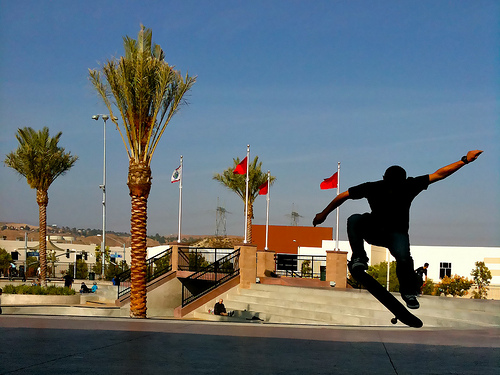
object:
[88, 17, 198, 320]
tree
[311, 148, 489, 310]
skateboarder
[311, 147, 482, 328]
trick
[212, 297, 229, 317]
guy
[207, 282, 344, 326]
step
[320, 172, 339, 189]
flag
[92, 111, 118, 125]
lights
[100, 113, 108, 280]
pole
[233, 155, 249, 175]
flag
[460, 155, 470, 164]
watch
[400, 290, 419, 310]
foot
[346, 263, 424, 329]
board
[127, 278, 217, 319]
walkway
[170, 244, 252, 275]
passage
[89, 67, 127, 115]
leaves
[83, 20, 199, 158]
leaves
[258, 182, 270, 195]
flag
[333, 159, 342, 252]
pole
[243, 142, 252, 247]
pole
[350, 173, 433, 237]
black shirt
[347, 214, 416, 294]
dark pants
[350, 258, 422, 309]
shoes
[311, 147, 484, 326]
jump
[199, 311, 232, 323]
cement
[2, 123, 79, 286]
tree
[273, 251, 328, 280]
railings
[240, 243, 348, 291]
entryway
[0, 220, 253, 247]
hill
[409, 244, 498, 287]
building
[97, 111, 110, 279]
tall pole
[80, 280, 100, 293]
people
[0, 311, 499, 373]
sidewalk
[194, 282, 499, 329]
stair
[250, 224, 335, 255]
roof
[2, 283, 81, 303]
bushes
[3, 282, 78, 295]
group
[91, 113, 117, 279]
light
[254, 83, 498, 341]
air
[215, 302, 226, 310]
shirt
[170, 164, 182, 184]
flag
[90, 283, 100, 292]
shirt